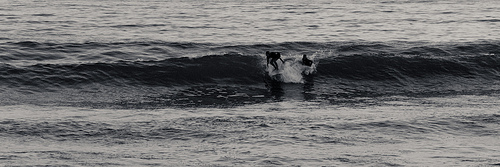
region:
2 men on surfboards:
[266, 30, 353, 95]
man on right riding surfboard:
[298, 45, 320, 91]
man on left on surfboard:
[251, 43, 283, 95]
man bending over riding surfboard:
[259, 32, 292, 116]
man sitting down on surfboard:
[298, 47, 325, 89]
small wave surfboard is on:
[354, 52, 423, 118]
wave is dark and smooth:
[49, 51, 132, 108]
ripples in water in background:
[125, 17, 200, 42]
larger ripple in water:
[35, 45, 83, 91]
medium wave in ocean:
[176, 36, 228, 145]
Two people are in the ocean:
[233, 27, 353, 93]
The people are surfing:
[197, 23, 369, 107]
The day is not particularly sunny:
[29, 9, 491, 153]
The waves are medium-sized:
[167, 27, 490, 104]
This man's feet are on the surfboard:
[245, 42, 292, 80]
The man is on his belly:
[293, 37, 320, 70]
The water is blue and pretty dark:
[52, 91, 273, 165]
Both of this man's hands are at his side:
[255, 43, 292, 85]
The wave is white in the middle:
[263, 49, 315, 84]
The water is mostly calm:
[20, 4, 495, 34]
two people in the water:
[251, 38, 326, 84]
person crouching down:
[257, 47, 293, 73]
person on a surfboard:
[254, 42, 299, 83]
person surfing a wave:
[248, 22, 290, 79]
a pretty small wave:
[14, 47, 499, 100]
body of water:
[0, 5, 498, 161]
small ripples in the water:
[110, 10, 180, 30]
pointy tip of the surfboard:
[265, 67, 276, 77]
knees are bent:
[266, 57, 281, 67]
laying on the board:
[297, 49, 313, 73]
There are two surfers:
[250, 40, 333, 91]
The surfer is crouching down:
[246, 35, 291, 86]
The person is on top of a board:
[261, 26, 286, 86]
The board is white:
[260, 65, 287, 82]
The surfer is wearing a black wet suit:
[245, 41, 290, 86]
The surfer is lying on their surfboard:
[290, 45, 320, 75]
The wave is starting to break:
[90, 30, 450, 105]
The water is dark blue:
[90, 51, 242, 156]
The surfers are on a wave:
[250, 36, 339, 98]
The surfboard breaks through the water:
[251, 40, 297, 92]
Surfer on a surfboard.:
[252, 27, 292, 94]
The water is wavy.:
[1, 2, 497, 163]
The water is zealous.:
[3, 3, 498, 159]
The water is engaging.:
[0, 0, 496, 163]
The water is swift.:
[2, 1, 497, 162]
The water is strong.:
[0, 0, 496, 160]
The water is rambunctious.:
[0, 0, 495, 160]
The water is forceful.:
[1, 0, 496, 160]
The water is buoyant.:
[2, 3, 497, 159]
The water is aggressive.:
[6, 2, 499, 161]